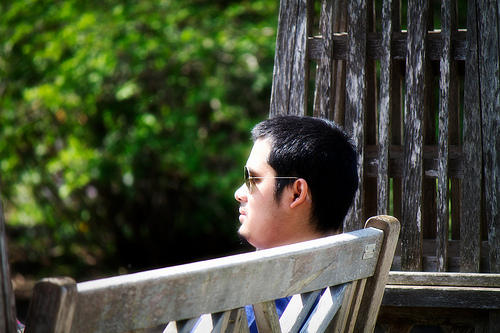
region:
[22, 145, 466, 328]
the bench is wooden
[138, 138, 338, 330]
the bench is wooden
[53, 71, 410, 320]
young man on bench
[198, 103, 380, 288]
man with black hair and sunglasses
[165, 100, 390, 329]
young man in blue shirt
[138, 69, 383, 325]
young man with short black hair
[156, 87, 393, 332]
man on bench wearing glasses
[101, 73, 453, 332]
man sitting near trees on a bench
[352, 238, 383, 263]
dedication marking on bench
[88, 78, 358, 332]
young man in blue shirt on bench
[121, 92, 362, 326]
man looking into the distance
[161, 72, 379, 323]
man sitting on a wooden bench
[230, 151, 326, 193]
man is wearing sunglasses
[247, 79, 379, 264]
man's hair is black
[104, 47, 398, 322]
the man is sitting down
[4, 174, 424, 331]
the bench is made of wood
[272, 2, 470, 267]
wood chipped off fence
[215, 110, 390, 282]
sun shining on man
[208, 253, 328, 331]
man's shirt is blue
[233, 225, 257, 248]
man has a beard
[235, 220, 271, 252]
man's beard is black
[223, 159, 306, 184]
glasses are gold colored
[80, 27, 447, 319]
a man with short hair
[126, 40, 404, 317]
a man wearing glasses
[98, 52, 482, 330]
a man wearing wire glasses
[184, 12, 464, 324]
a man wearing sunglasses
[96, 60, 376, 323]
a man sitting down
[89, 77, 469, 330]
a man is sitting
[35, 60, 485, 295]
a man on a wooden bench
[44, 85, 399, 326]
a man sitting on a wooden bench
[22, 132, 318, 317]
a wooden bench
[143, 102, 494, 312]
a woman bench with a man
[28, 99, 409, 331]
man sitting on bench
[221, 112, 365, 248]
man has black hair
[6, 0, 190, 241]
green trees are in front if man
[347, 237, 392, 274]
little sign in on the bench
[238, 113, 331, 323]
man is wearing blue shirt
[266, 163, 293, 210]
man has black sideburns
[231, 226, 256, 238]
man has hair on his chin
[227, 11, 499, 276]
wood building with slats is next to man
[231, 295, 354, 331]
sunlight is showing on the bench